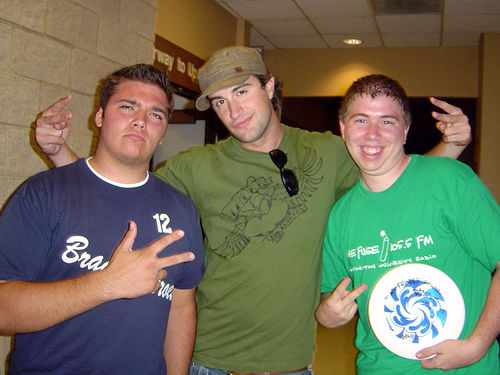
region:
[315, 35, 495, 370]
Young man wearing light green shirt.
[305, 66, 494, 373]
Young man holding white frisbee.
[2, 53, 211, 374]
Young man wearing blue shirt.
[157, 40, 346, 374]
Young man wearing sage shirt.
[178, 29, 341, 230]
Young man wearing hat.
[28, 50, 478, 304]
All young men holding up hand signs.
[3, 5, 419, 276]
Young men standing next to brick wall.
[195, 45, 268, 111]
the green hat on the man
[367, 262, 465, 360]
the white frisbee the boy is holding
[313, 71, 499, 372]
the boy holding the frisbee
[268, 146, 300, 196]
the sunglasses on the shirt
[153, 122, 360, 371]
the military green shirt on the man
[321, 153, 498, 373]
the bright green shirt on the boy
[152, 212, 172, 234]
the number 12 on the shirt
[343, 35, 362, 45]
the light in the ceiling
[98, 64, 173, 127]
the hair is brown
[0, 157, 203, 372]
the shirt is blue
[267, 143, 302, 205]
sunglasses in a man's shirt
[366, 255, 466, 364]
white and blue frisbee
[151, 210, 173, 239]
number 12 on a blue shirt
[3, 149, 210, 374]
blue tee shirt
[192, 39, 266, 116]
green hat on a man's head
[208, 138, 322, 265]
design on a man's shirt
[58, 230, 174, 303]
writing on a blue shirt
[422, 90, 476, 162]
left hand of the middle person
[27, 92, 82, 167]
right hand of the middle person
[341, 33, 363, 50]
light in the ceiling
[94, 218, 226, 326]
boy showing 3 fingers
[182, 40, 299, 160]
boy wearing green hat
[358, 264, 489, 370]
Boy holding frisbee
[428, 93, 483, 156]
boy holding up 2 fingers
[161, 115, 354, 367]
boy wearing a green shirt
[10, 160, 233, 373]
boy wearing a blue shirt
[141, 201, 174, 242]
Number 12 on shirt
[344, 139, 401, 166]
boy smiling with teeth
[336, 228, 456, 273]
Shirt advertises a radio station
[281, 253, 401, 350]
Boy holding up 2 fingers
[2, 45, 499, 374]
three young men posing together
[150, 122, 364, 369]
a dark green printed t-shirt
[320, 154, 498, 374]
a bright green printed t-shirt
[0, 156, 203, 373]
a dark blue printed t-shirt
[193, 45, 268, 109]
a dark green hat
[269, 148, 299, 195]
a pair of sunglasses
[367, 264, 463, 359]
a white and blue frisbee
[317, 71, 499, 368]
a young man holding a frisbee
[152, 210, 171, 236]
printed number 12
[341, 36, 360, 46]
a recessed overhead light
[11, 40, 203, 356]
man wearing blue t-shirt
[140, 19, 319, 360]
man is wearing olive green t-shirt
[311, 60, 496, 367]
man is wearing lime green t-shirt